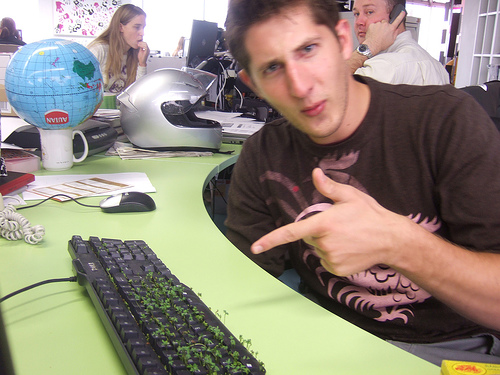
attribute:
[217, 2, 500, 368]
man — pointing, young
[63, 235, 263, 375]
keyboard — black, green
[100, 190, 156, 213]
mouse — wired, black, white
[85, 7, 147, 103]
woman — blonde, young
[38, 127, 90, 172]
mug — white, large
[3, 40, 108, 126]
globe — earth, sitting, blue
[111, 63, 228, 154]
helmet — silver, large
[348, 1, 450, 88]
man — looking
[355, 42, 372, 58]
watch — silver, gray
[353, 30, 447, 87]
shirt — white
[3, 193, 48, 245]
cord — twisted, tangled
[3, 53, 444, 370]
desk — curved, green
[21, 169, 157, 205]
paper — white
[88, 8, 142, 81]
hair — blonde